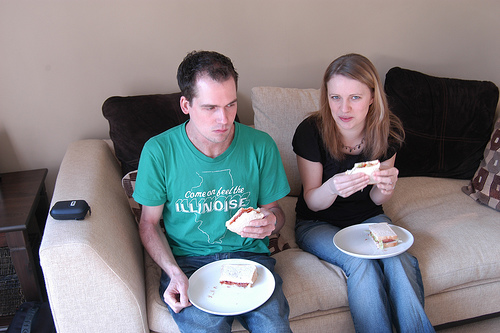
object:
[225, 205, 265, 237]
sandwiches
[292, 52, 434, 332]
woman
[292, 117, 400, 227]
top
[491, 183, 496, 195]
brown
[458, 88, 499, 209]
pillow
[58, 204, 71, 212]
black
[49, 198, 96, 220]
phone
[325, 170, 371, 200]
hand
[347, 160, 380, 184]
sandwich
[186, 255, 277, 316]
plate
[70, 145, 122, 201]
cream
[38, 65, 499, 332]
sofa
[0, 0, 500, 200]
white wall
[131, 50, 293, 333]
man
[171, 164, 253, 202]
chest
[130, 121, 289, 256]
green shirt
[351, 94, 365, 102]
eyes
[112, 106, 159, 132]
dark chocolate brown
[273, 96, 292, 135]
beige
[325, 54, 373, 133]
head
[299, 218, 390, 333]
leg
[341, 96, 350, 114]
nose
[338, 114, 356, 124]
mouth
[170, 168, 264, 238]
illinois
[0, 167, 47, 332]
table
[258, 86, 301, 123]
tan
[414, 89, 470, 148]
dark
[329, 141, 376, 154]
necklace